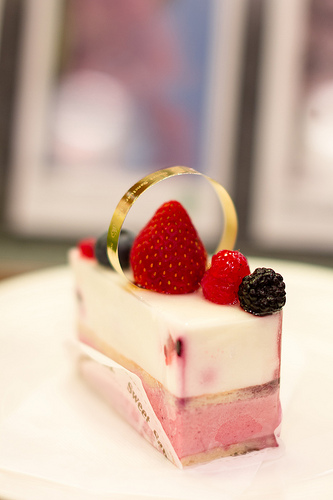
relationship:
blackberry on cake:
[239, 266, 286, 317] [68, 165, 285, 467]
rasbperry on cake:
[200, 250, 251, 306] [68, 165, 285, 467]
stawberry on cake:
[130, 200, 209, 293] [68, 165, 285, 467]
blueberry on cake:
[96, 228, 136, 270] [68, 165, 285, 467]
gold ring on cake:
[105, 166, 238, 292] [68, 165, 285, 467]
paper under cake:
[71, 334, 286, 470] [68, 165, 285, 467]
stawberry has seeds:
[130, 200, 209, 293] [130, 200, 207, 295]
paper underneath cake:
[71, 334, 286, 470] [68, 165, 285, 467]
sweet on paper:
[124, 380, 153, 426] [71, 334, 286, 470]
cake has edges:
[68, 165, 285, 467] [69, 243, 284, 470]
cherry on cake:
[80, 239, 99, 261] [68, 165, 285, 467]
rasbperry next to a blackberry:
[200, 250, 251, 306] [239, 266, 286, 317]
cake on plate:
[68, 165, 285, 467] [0, 255, 332, 498]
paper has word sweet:
[71, 334, 286, 470] [124, 380, 153, 426]